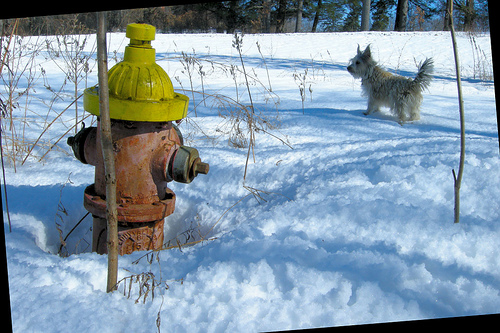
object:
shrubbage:
[230, 30, 257, 113]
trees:
[0, 3, 214, 34]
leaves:
[113, 270, 169, 332]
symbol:
[118, 228, 157, 256]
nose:
[346, 64, 356, 72]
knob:
[171, 145, 210, 185]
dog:
[346, 42, 437, 126]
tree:
[94, 8, 119, 293]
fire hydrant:
[66, 23, 209, 254]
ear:
[363, 43, 371, 55]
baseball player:
[445, 0, 466, 225]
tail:
[411, 55, 435, 94]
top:
[82, 22, 188, 123]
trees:
[217, 0, 282, 33]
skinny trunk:
[96, 9, 119, 297]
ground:
[0, 30, 500, 322]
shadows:
[0, 51, 500, 315]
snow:
[1, 31, 498, 330]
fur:
[366, 69, 407, 97]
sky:
[226, 0, 484, 30]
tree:
[295, 0, 302, 31]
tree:
[358, 1, 370, 31]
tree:
[370, 0, 391, 30]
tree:
[340, 0, 363, 30]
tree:
[320, 0, 345, 30]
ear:
[355, 43, 361, 54]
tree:
[449, 1, 468, 224]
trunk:
[444, 0, 466, 223]